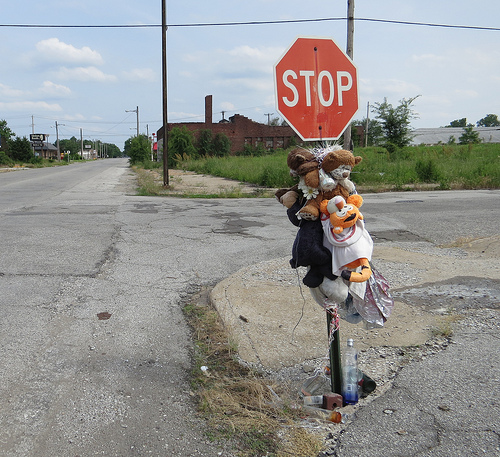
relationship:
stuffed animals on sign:
[278, 148, 379, 311] [273, 33, 361, 143]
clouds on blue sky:
[21, 31, 114, 115] [0, 0, 499, 152]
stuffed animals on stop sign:
[249, 20, 399, 163] [243, 129, 399, 344]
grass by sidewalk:
[182, 303, 287, 438] [31, 130, 206, 426]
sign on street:
[273, 33, 361, 143] [0, 155, 499, 455]